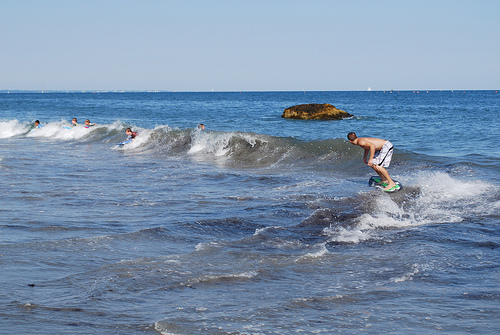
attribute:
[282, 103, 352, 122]
island — small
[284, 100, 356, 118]
rock — brown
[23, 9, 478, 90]
sky — blue, clear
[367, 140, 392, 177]
shorts — black, white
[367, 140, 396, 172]
shorts — board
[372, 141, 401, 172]
stripe — black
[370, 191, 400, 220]
foam — white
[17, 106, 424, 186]
waves — small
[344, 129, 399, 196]
man — shirtless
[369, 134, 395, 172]
shorts — gray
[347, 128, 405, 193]
man — shirtless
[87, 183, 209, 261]
water — large body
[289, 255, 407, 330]
water — large body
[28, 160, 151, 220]
water — large body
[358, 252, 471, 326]
water — large body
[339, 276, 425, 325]
water — large body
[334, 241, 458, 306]
water — large body